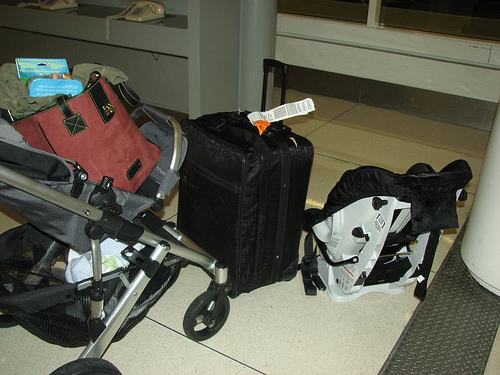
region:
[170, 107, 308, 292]
a solid black piece of luggage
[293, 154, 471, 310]
a black and white car seat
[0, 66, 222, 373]
a grey baby stroller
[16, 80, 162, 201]
a maroon red bag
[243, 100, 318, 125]
a white luggage sticker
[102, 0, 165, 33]
a beige corded telephone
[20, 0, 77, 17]
a beige corded telephone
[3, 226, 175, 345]
a black mesh basket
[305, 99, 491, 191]
a large white floor tile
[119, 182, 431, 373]
a large white floor tile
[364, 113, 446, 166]
The floor is brown.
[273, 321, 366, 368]
The floor is white.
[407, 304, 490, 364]
Black on the floor.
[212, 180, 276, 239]
The suitcase is black.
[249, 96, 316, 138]
Tag on the suitcase.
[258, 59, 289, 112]
The handle is black.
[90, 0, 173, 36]
Telephone on a shelf.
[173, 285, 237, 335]
The wheel is black.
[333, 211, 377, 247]
Back of the car seat is white.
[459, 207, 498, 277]
The pole is white.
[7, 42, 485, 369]
this is a cluttered area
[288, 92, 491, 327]
this is a baby seat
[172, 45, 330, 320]
a suitcase with a handle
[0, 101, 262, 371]
a baby stroller on the floor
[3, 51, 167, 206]
a maroon bag stuffed with goods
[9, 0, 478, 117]
a counter with telephones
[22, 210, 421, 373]
a picture of the floor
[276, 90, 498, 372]
the floor is white and another part is tan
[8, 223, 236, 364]
the bottom of the stroller is cluttered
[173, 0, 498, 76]
a window seal in the background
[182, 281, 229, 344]
Swivel wheels on a stroller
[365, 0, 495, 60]
Base of a windowsill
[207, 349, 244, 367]
Seam in a tiled floor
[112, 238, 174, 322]
Aluminum frame of a baby stroller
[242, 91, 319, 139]
Luggage tags for an airport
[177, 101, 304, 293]
Travel bag sitting on the floor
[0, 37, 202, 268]
Baby stroller filled with luggage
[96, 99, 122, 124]
Latch on handbag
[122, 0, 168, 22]
Old-style telephone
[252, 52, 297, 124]
Handle on a travel bag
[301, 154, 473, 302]
black and gray carseat on a floor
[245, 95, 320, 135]
tags on a black luggage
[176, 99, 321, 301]
black luggage on a floor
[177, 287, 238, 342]
black wheel on a stroller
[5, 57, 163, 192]
red filled bag on a stroller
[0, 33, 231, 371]
stroller filled with lots of items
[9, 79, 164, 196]
red and black bag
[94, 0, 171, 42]
telephone on a counter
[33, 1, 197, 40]
two telephones on a counter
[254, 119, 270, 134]
orange tag attached a luggage